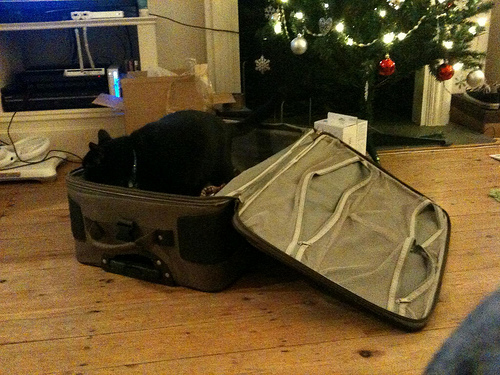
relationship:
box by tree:
[94, 71, 235, 114] [249, 0, 497, 95]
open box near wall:
[121, 55, 215, 138] [158, 2, 240, 71]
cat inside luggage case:
[83, 84, 293, 197] [62, 106, 452, 333]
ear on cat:
[94, 127, 112, 144] [82, 110, 234, 195]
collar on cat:
[118, 119, 144, 204] [64, 96, 236, 199]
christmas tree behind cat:
[237, 5, 494, 152] [73, 94, 290, 184]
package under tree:
[404, 59, 454, 130] [253, 0, 488, 173]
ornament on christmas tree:
[286, 32, 310, 59] [253, 0, 500, 131]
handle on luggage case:
[80, 214, 152, 258] [61, 106, 453, 335]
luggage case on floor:
[91, 110, 266, 295] [0, 123, 500, 374]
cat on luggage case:
[83, 109, 273, 189] [62, 106, 452, 333]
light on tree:
[380, 30, 400, 51] [232, 2, 499, 172]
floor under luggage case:
[0, 137, 499, 373] [61, 106, 453, 335]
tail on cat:
[226, 69, 306, 140] [73, 81, 293, 198]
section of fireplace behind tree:
[242, 50, 330, 109] [253, 0, 488, 173]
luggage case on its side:
[62, 106, 452, 333] [222, 184, 401, 302]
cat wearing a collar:
[83, 84, 293, 197] [137, 93, 341, 178]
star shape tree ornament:
[258, 45, 268, 74] [319, 49, 409, 86]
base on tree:
[348, 63, 429, 138] [253, 0, 488, 173]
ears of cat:
[78, 123, 118, 158] [243, 70, 310, 153]